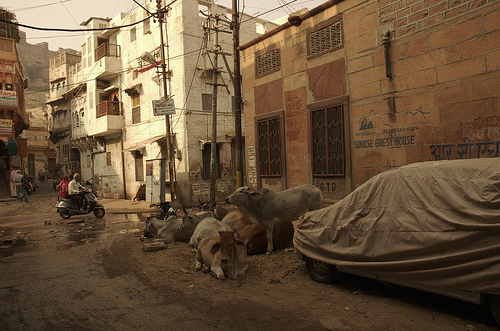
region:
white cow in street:
[228, 187, 323, 243]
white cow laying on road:
[195, 220, 276, 290]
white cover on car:
[306, 173, 491, 295]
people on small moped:
[57, 172, 127, 223]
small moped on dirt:
[56, 180, 128, 240]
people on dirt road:
[12, 170, 38, 208]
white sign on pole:
[153, 93, 188, 130]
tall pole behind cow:
[206, 70, 249, 209]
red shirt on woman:
[55, 182, 70, 207]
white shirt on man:
[64, 165, 86, 198]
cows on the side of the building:
[137, 181, 325, 308]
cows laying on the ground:
[129, 194, 234, 286]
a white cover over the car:
[295, 135, 499, 322]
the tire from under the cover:
[302, 252, 337, 282]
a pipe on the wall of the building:
[371, 29, 400, 83]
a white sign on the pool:
[150, 94, 178, 120]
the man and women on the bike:
[50, 173, 113, 225]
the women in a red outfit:
[52, 169, 76, 203]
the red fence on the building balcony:
[95, 100, 128, 114]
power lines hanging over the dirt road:
[0, 4, 249, 61]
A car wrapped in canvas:
[290, 149, 498, 326]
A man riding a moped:
[50, 168, 108, 225]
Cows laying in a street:
[138, 208, 253, 283]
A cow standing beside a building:
[219, 168, 331, 263]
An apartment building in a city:
[42, 0, 288, 217]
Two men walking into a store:
[0, 83, 38, 206]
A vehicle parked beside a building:
[288, 145, 498, 324]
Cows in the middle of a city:
[138, 181, 331, 288]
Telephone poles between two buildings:
[148, 0, 246, 205]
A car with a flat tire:
[289, 147, 499, 329]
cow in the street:
[223, 168, 340, 255]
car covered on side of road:
[286, 138, 493, 317]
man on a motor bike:
[53, 167, 109, 236]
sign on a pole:
[148, 91, 178, 120]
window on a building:
[306, 98, 368, 190]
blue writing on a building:
[354, 129, 419, 155]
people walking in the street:
[5, 165, 36, 207]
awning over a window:
[124, 138, 148, 158]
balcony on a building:
[73, 84, 125, 141]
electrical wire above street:
[28, 16, 151, 37]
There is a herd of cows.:
[133, 188, 338, 259]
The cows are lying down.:
[161, 194, 258, 268]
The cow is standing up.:
[225, 184, 326, 231]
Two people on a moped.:
[48, 161, 98, 215]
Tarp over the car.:
[291, 140, 498, 297]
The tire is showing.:
[296, 247, 338, 284]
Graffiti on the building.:
[423, 130, 498, 171]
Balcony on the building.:
[81, 100, 122, 134]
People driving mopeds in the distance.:
[34, 157, 61, 190]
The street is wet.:
[35, 210, 198, 325]